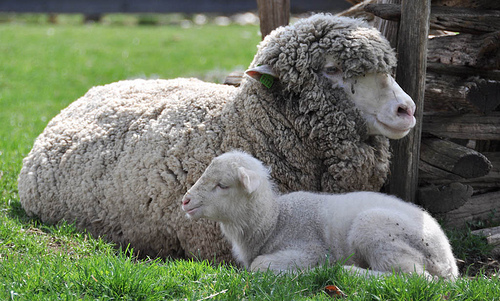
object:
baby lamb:
[172, 147, 464, 291]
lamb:
[177, 150, 468, 285]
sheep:
[19, 15, 410, 255]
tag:
[258, 74, 279, 91]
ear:
[246, 67, 279, 83]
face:
[181, 157, 239, 221]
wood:
[429, 34, 484, 73]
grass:
[363, 285, 387, 298]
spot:
[394, 221, 402, 228]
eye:
[217, 181, 230, 190]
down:
[226, 260, 447, 279]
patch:
[55, 49, 84, 66]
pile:
[416, 137, 494, 176]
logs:
[425, 70, 497, 115]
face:
[327, 41, 414, 142]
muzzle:
[371, 95, 418, 142]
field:
[0, 16, 243, 301]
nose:
[177, 191, 192, 207]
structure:
[256, 0, 499, 261]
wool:
[127, 113, 205, 153]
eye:
[321, 63, 341, 74]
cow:
[81, 10, 100, 23]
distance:
[0, 3, 283, 51]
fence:
[256, 2, 295, 21]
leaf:
[320, 281, 346, 297]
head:
[251, 13, 422, 144]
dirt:
[31, 229, 67, 247]